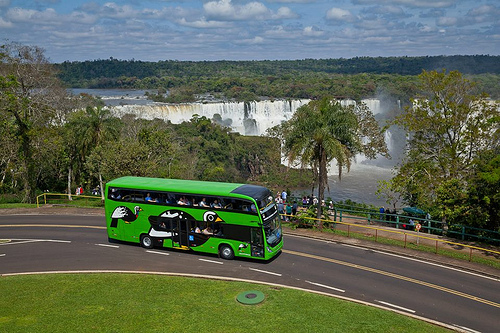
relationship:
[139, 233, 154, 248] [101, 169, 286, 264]
wheel of bus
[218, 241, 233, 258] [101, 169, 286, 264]
wheel of bus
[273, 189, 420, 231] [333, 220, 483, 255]
people at sidewalk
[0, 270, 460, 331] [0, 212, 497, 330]
grass at street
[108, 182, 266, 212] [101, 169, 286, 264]
windows on bus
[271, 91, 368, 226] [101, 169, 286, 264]
tree behind bus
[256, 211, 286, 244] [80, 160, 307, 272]
window of bus